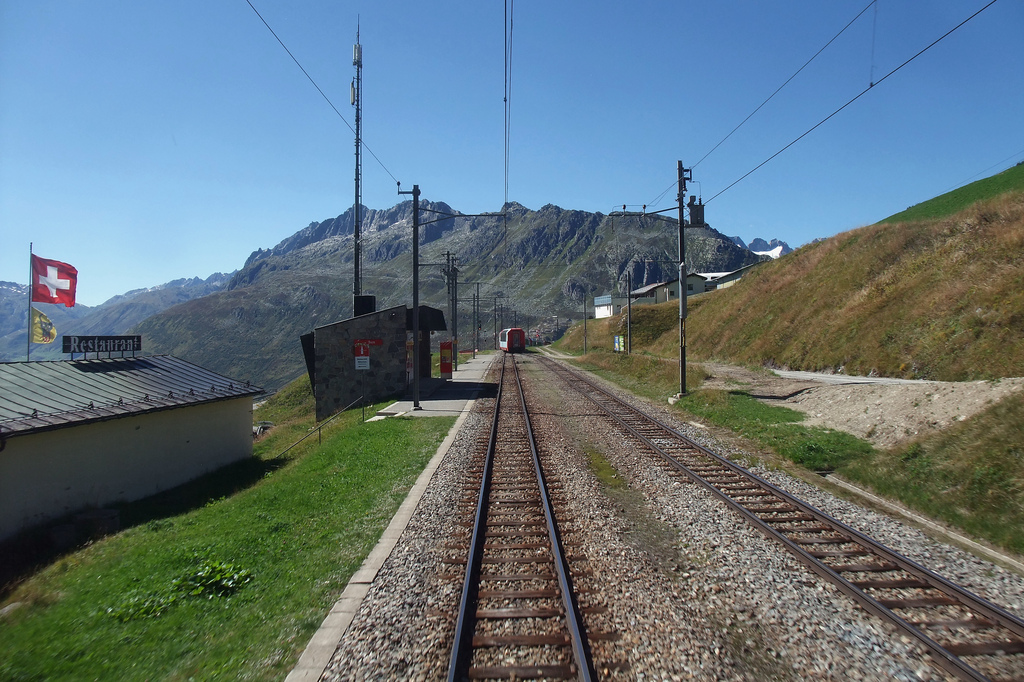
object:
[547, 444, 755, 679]
gravel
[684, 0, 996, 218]
wires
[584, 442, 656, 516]
grass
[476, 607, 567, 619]
planks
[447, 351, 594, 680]
rail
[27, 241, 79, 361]
flag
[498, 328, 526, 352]
train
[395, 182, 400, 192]
light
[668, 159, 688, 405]
pole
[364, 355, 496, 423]
ground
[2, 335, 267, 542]
building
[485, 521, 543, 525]
plank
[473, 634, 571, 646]
plank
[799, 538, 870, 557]
plank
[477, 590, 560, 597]
plank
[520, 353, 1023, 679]
track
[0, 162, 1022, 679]
ground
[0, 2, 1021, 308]
air